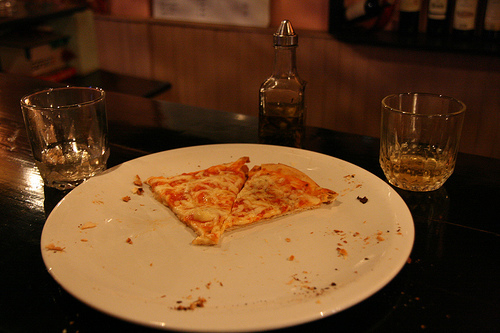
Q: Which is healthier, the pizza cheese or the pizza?
A: The cheese is healthier than the pizza.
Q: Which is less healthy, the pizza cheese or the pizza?
A: The pizza is less healthy than the cheese.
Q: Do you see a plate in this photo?
A: Yes, there is a plate.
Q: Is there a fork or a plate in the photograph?
A: Yes, there is a plate.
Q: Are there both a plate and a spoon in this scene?
A: No, there is a plate but no spoons.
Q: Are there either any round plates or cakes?
A: Yes, there is a round plate.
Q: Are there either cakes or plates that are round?
A: Yes, the plate is round.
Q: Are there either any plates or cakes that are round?
A: Yes, the plate is round.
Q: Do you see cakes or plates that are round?
A: Yes, the plate is round.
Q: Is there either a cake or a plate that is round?
A: Yes, the plate is round.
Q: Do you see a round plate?
A: Yes, there is a round plate.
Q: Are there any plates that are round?
A: Yes, there is a plate that is round.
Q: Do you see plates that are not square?
A: Yes, there is a round plate.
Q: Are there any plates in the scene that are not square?
A: Yes, there is a round plate.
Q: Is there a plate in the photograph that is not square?
A: Yes, there is a round plate.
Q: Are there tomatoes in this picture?
A: No, there are no tomatoes.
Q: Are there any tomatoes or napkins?
A: No, there are no tomatoes or napkins.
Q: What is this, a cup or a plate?
A: This is a plate.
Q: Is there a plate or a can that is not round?
A: No, there is a plate but it is round.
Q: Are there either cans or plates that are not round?
A: No, there is a plate but it is round.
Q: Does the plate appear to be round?
A: Yes, the plate is round.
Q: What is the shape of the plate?
A: The plate is round.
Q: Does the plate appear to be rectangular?
A: No, the plate is round.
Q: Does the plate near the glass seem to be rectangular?
A: No, the plate is round.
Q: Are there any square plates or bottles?
A: No, there is a plate but it is round.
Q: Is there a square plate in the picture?
A: No, there is a plate but it is round.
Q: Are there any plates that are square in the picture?
A: No, there is a plate but it is round.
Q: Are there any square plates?
A: No, there is a plate but it is round.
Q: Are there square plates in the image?
A: No, there is a plate but it is round.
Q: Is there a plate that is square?
A: No, there is a plate but it is round.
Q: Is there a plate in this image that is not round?
A: No, there is a plate but it is round.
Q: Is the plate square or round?
A: The plate is round.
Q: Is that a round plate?
A: Yes, that is a round plate.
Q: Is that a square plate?
A: No, that is a round plate.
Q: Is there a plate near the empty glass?
A: Yes, there is a plate near the glass.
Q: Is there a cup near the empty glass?
A: No, there is a plate near the glass.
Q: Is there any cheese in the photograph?
A: Yes, there is cheese.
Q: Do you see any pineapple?
A: No, there are no pineapples.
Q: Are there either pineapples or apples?
A: No, there are no pineapples or apples.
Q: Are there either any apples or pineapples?
A: No, there are no pineapples or apples.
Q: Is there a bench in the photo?
A: Yes, there is a bench.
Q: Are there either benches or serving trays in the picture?
A: Yes, there is a bench.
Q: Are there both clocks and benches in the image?
A: No, there is a bench but no clocks.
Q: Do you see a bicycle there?
A: No, there are no bicycles.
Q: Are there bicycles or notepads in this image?
A: No, there are no bicycles or notepads.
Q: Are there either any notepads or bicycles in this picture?
A: No, there are no bicycles or notepads.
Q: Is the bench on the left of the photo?
A: Yes, the bench is on the left of the image.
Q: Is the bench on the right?
A: No, the bench is on the left of the image.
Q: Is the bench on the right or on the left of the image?
A: The bench is on the left of the image.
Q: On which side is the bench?
A: The bench is on the left of the image.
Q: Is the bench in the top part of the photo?
A: Yes, the bench is in the top of the image.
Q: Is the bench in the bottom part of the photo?
A: No, the bench is in the top of the image.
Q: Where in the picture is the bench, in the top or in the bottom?
A: The bench is in the top of the image.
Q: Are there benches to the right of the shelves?
A: Yes, there is a bench to the right of the shelves.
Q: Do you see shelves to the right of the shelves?
A: No, there is a bench to the right of the shelves.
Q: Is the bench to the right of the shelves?
A: Yes, the bench is to the right of the shelves.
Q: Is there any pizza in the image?
A: Yes, there is a pizza.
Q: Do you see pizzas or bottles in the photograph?
A: Yes, there is a pizza.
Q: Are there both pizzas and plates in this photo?
A: Yes, there are both a pizza and a plate.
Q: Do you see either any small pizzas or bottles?
A: Yes, there is a small pizza.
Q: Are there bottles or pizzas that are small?
A: Yes, the pizza is small.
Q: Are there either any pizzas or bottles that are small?
A: Yes, the pizza is small.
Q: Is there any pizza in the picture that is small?
A: Yes, there is a small pizza.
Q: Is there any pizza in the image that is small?
A: Yes, there is a pizza that is small.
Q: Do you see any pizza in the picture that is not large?
A: Yes, there is a small pizza.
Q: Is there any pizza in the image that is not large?
A: Yes, there is a small pizza.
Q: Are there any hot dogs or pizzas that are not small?
A: No, there is a pizza but it is small.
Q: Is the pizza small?
A: Yes, the pizza is small.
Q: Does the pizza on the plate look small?
A: Yes, the pizza is small.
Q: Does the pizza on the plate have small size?
A: Yes, the pizza is small.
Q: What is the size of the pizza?
A: The pizza is small.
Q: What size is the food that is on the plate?
A: The pizza is small.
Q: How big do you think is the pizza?
A: The pizza is small.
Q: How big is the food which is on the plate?
A: The pizza is small.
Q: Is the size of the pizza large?
A: No, the pizza is small.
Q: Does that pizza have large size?
A: No, the pizza is small.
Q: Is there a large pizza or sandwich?
A: No, there is a pizza but it is small.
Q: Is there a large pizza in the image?
A: No, there is a pizza but it is small.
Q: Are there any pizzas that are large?
A: No, there is a pizza but it is small.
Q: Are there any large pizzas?
A: No, there is a pizza but it is small.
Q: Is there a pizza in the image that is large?
A: No, there is a pizza but it is small.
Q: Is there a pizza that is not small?
A: No, there is a pizza but it is small.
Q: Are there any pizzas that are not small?
A: No, there is a pizza but it is small.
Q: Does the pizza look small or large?
A: The pizza is small.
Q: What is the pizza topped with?
A: The pizza is topped with cheese.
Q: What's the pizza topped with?
A: The pizza is topped with cheese.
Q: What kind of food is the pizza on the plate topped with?
A: The pizza is topped with cheese.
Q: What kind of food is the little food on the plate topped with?
A: The pizza is topped with cheese.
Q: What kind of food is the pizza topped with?
A: The pizza is topped with cheese.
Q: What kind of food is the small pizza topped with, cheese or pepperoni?
A: The pizza is topped with cheese.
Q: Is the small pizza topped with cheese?
A: Yes, the pizza is topped with cheese.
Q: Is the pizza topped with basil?
A: No, the pizza is topped with cheese.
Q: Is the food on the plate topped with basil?
A: No, the pizza is topped with cheese.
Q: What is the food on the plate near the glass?
A: The food is a pizza.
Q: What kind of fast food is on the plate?
A: The food is a pizza.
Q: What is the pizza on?
A: The pizza is on the plate.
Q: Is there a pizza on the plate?
A: Yes, there is a pizza on the plate.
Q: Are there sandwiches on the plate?
A: No, there is a pizza on the plate.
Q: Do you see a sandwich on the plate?
A: No, there is a pizza on the plate.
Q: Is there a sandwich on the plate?
A: No, there is a pizza on the plate.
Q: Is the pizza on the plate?
A: Yes, the pizza is on the plate.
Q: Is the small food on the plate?
A: Yes, the pizza is on the plate.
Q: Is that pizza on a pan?
A: No, the pizza is on the plate.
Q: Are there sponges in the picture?
A: No, there are no sponges.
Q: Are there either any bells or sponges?
A: No, there are no sponges or bells.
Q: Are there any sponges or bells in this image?
A: No, there are no sponges or bells.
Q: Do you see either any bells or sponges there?
A: No, there are no sponges or bells.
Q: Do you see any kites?
A: No, there are no kites.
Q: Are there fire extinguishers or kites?
A: No, there are no kites or fire extinguishers.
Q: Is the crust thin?
A: Yes, the crust is thin.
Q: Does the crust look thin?
A: Yes, the crust is thin.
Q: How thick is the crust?
A: The crust is thin.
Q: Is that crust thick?
A: No, the crust is thin.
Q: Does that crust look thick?
A: No, the crust is thin.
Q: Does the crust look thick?
A: No, the crust is thin.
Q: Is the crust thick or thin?
A: The crust is thin.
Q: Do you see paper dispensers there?
A: No, there are no paper dispensers.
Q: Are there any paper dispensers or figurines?
A: No, there are no paper dispensers or figurines.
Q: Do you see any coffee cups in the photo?
A: No, there are no coffee cups.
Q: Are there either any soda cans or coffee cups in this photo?
A: No, there are no coffee cups or soda cans.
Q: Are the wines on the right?
A: Yes, the wines are on the right of the image.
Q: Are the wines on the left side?
A: No, the wines are on the right of the image.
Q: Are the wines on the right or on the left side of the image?
A: The wines are on the right of the image.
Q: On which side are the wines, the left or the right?
A: The wines are on the right of the image.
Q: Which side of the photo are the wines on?
A: The wines are on the right of the image.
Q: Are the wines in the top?
A: Yes, the wines are in the top of the image.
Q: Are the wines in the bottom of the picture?
A: No, the wines are in the top of the image.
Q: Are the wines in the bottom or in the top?
A: The wines are in the top of the image.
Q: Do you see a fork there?
A: No, there are no forks.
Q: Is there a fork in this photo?
A: No, there are no forks.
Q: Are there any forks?
A: No, there are no forks.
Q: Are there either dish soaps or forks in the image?
A: No, there are no forks or dish soaps.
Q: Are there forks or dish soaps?
A: No, there are no forks or dish soaps.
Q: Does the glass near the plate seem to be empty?
A: Yes, the glass is empty.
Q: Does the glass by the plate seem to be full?
A: No, the glass is empty.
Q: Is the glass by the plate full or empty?
A: The glass is empty.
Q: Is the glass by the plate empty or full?
A: The glass is empty.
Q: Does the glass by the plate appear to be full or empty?
A: The glass is empty.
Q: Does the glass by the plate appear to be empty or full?
A: The glass is empty.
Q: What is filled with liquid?
A: The glass is filled with liquid.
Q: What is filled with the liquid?
A: The glass is filled with liquid.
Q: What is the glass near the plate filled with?
A: The glass is filled with liquid.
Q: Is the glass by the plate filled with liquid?
A: Yes, the glass is filled with liquid.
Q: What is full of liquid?
A: The glass is full of liquid.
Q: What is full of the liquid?
A: The glass is full of liquid.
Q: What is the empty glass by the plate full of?
A: The glass is full of liquid.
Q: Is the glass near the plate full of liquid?
A: Yes, the glass is full of liquid.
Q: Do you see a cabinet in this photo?
A: No, there are no cabinets.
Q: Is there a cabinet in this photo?
A: No, there are no cabinets.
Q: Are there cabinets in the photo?
A: No, there are no cabinets.